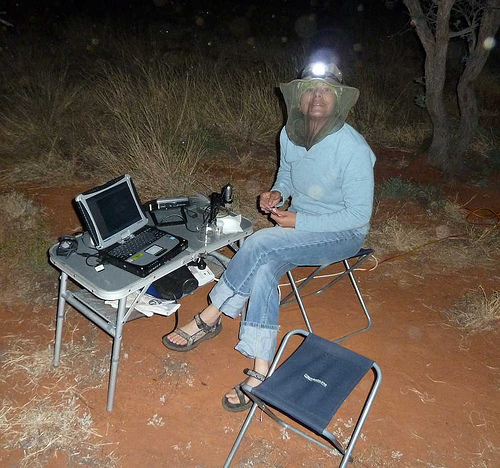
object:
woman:
[160, 47, 374, 419]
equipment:
[49, 170, 239, 296]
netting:
[269, 83, 364, 146]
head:
[297, 56, 341, 119]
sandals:
[152, 380, 207, 415]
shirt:
[269, 120, 376, 231]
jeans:
[189, 217, 367, 353]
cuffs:
[237, 324, 280, 362]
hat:
[280, 51, 360, 97]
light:
[308, 62, 329, 79]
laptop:
[70, 171, 192, 278]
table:
[45, 189, 254, 409]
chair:
[278, 240, 380, 344]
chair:
[225, 326, 405, 466]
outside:
[0, 3, 499, 467]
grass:
[22, 160, 46, 182]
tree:
[399, 5, 456, 163]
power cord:
[382, 231, 477, 263]